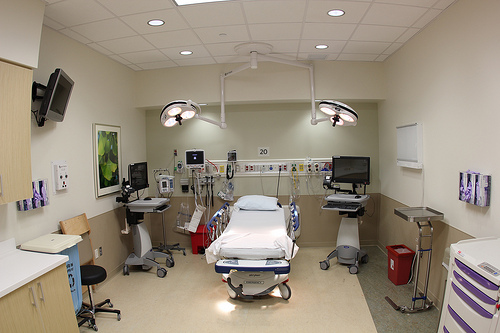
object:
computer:
[331, 154, 371, 185]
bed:
[203, 193, 303, 302]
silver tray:
[392, 205, 446, 223]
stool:
[76, 264, 124, 332]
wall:
[0, 23, 149, 294]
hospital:
[0, 0, 498, 332]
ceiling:
[44, 0, 461, 74]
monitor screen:
[330, 157, 369, 183]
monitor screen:
[186, 151, 205, 166]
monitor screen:
[130, 161, 150, 191]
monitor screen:
[47, 71, 75, 118]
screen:
[396, 124, 419, 162]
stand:
[318, 202, 371, 274]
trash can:
[190, 224, 215, 255]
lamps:
[161, 102, 196, 129]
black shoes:
[414, 46, 476, 114]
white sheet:
[204, 209, 299, 265]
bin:
[17, 233, 87, 314]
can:
[386, 245, 414, 287]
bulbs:
[313, 44, 329, 52]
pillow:
[234, 194, 279, 211]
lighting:
[326, 8, 343, 18]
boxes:
[455, 169, 490, 208]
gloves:
[458, 170, 491, 207]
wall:
[375, 2, 498, 314]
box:
[394, 121, 422, 169]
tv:
[31, 66, 77, 127]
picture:
[94, 125, 125, 197]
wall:
[151, 53, 386, 260]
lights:
[180, 50, 196, 55]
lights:
[315, 44, 330, 51]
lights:
[145, 18, 167, 28]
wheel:
[277, 280, 293, 301]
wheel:
[224, 287, 240, 302]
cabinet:
[0, 250, 81, 332]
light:
[313, 99, 358, 129]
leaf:
[100, 156, 118, 180]